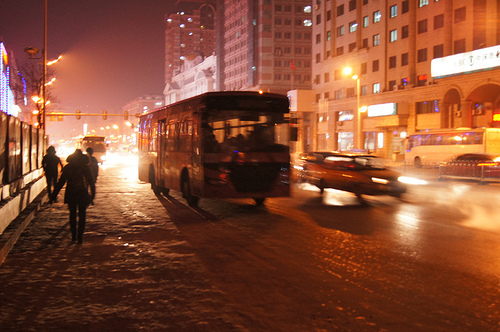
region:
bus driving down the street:
[125, 72, 308, 214]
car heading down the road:
[296, 139, 413, 214]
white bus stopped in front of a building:
[395, 117, 497, 182]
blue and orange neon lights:
[1, 43, 47, 118]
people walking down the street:
[37, 136, 107, 249]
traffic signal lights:
[42, 102, 156, 129]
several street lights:
[26, 38, 68, 125]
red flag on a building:
[276, 52, 313, 104]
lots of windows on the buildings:
[169, 12, 484, 86]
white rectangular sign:
[427, 47, 497, 82]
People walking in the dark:
[38, 131, 145, 226]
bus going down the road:
[123, 90, 293, 231]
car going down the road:
[312, 119, 380, 231]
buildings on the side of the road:
[237, 5, 491, 210]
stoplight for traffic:
[49, 90, 139, 150]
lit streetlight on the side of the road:
[324, 44, 391, 129]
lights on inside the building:
[339, 6, 424, 59]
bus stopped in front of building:
[389, 126, 487, 196]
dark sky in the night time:
[39, 11, 187, 133]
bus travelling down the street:
[121, 70, 269, 205]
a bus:
[211, 131, 266, 227]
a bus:
[193, 96, 250, 181]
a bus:
[176, 104, 222, 199]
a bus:
[141, 121, 236, 175]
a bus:
[211, 136, 318, 256]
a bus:
[176, 83, 272, 264]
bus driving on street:
[124, 84, 311, 214]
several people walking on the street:
[42, 141, 110, 238]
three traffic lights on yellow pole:
[40, 70, 144, 147]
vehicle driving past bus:
[315, 127, 407, 217]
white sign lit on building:
[418, 32, 496, 84]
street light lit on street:
[330, 52, 382, 166]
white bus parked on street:
[394, 98, 498, 190]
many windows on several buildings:
[182, 32, 440, 110]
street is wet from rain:
[100, 87, 450, 305]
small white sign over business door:
[348, 88, 415, 150]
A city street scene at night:
[9, 18, 484, 305]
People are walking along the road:
[36, 139, 108, 236]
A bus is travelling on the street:
[132, 88, 302, 207]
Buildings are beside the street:
[308, 9, 498, 125]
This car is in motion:
[303, 150, 420, 205]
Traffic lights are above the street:
[47, 103, 134, 125]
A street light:
[338, 57, 372, 151]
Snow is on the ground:
[39, 243, 183, 321]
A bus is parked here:
[401, 121, 498, 168]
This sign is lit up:
[429, 42, 499, 82]